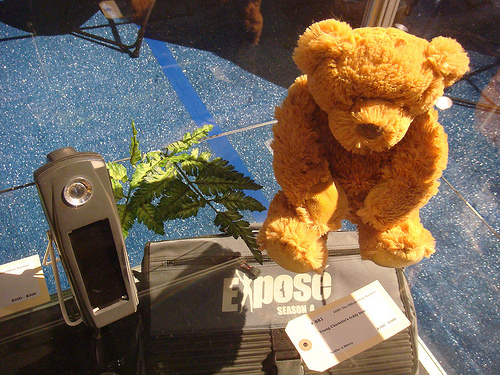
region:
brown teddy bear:
[294, 37, 421, 198]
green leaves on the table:
[119, 136, 200, 216]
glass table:
[438, 247, 497, 316]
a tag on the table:
[283, 306, 412, 361]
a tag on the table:
[3, 261, 42, 308]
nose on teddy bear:
[346, 115, 383, 139]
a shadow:
[166, 261, 241, 339]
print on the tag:
[310, 317, 375, 333]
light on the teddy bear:
[269, 214, 324, 269]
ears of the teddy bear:
[296, 16, 462, 77]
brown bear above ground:
[276, 16, 475, 213]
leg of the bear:
[249, 211, 338, 301]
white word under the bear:
[196, 262, 346, 324]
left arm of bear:
[377, 116, 459, 229]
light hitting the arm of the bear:
[419, 113, 461, 210]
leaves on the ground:
[156, 126, 234, 220]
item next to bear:
[42, 119, 137, 332]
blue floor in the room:
[13, 85, 113, 129]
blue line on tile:
[127, 73, 214, 128]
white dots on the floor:
[59, 58, 114, 113]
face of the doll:
[303, 36, 430, 148]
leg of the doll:
[262, 196, 345, 277]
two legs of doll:
[248, 182, 445, 288]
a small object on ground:
[39, 132, 176, 339]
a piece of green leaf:
[125, 124, 307, 258]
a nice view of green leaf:
[138, 141, 273, 293]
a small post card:
[278, 280, 403, 371]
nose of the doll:
[345, 106, 389, 153]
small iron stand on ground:
[81, 15, 186, 61]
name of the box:
[204, 252, 379, 329]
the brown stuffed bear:
[263, 21, 467, 282]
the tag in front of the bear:
[286, 279, 407, 370]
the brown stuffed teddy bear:
[257, 18, 470, 282]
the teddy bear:
[261, 12, 464, 277]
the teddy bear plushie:
[260, 7, 475, 287]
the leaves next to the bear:
[102, 120, 265, 266]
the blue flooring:
[18, 50, 155, 152]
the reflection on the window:
[462, 45, 498, 180]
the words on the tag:
[320, 308, 377, 344]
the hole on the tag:
[297, 335, 311, 352]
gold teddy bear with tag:
[268, 16, 475, 269]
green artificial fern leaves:
[119, 139, 260, 232]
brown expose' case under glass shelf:
[138, 229, 427, 374]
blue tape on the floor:
[149, 70, 268, 157]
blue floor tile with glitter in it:
[29, 62, 115, 145]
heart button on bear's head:
[390, 35, 409, 53]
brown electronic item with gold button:
[26, 135, 143, 335]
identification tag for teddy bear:
[286, 276, 412, 369]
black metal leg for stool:
[64, 0, 171, 65]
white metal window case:
[416, 330, 453, 374]